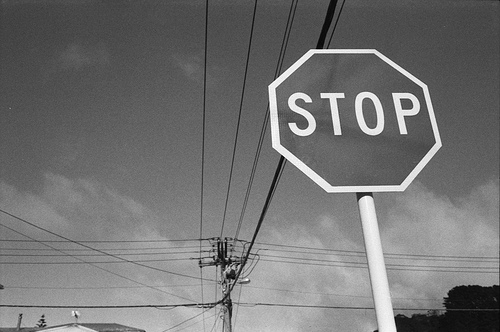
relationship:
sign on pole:
[242, 23, 467, 192] [344, 195, 411, 332]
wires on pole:
[198, 217, 260, 245] [344, 195, 411, 332]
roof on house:
[81, 314, 140, 331] [9, 314, 148, 330]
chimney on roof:
[12, 312, 31, 331] [81, 314, 140, 331]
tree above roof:
[35, 308, 54, 329] [81, 314, 140, 331]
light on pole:
[231, 273, 266, 298] [202, 243, 253, 325]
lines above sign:
[276, 9, 339, 42] [242, 23, 467, 192]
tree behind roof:
[35, 308, 54, 329] [81, 314, 140, 331]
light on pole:
[233, 275, 253, 285] [344, 195, 411, 332]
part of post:
[374, 243, 378, 247] [344, 195, 411, 332]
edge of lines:
[322, 28, 325, 35] [276, 9, 339, 42]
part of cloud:
[103, 209, 108, 211] [14, 193, 197, 311]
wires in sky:
[198, 217, 260, 245] [29, 37, 214, 227]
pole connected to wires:
[202, 243, 253, 325] [198, 217, 260, 245]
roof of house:
[81, 314, 140, 331] [9, 314, 148, 330]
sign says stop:
[242, 23, 467, 192] [267, 79, 450, 174]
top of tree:
[36, 310, 48, 319] [35, 308, 54, 329]